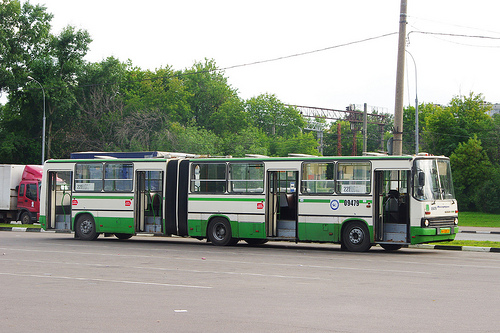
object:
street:
[0, 220, 500, 331]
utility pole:
[391, 0, 408, 155]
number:
[343, 199, 359, 207]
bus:
[38, 156, 459, 252]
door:
[375, 170, 410, 244]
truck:
[0, 165, 69, 225]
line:
[0, 271, 212, 290]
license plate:
[441, 229, 451, 233]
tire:
[75, 214, 100, 241]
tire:
[207, 216, 240, 245]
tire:
[341, 221, 372, 252]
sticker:
[72, 199, 79, 205]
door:
[265, 170, 297, 239]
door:
[136, 171, 164, 233]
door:
[48, 171, 72, 230]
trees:
[0, 0, 326, 157]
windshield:
[412, 157, 456, 201]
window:
[74, 162, 104, 192]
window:
[104, 162, 134, 192]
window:
[190, 162, 227, 193]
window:
[228, 161, 264, 193]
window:
[300, 161, 334, 194]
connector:
[164, 159, 189, 236]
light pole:
[25, 75, 46, 165]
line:
[0, 253, 324, 279]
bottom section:
[71, 227, 434, 252]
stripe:
[72, 195, 372, 204]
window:
[336, 160, 371, 194]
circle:
[329, 199, 339, 211]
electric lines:
[0, 27, 400, 95]